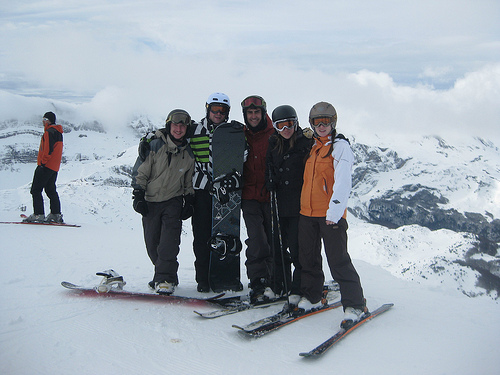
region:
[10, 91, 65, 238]
skier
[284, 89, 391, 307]
skier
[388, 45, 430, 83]
white clouds in blue sky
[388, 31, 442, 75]
white clouds in blue sky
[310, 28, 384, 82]
white clouds in blue sky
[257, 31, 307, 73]
white clouds in blue sky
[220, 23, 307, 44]
white clouds in blue sky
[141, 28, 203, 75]
white clouds in blue sky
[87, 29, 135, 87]
white clouds in blue sky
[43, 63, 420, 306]
people in the photo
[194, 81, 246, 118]
white helmet on the man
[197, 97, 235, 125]
goggles on man's head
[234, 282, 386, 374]
skis on the ground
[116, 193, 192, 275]
pants on the person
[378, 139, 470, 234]
mountains in the background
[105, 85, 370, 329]
5 people posing for a picture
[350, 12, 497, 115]
clouds in a blue and white sky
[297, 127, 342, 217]
Orange winter jacket with white arm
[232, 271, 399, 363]
2 skis and white boots on top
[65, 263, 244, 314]
Snow board on snow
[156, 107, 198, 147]
Man smiling at camera with brown visor.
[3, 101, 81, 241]
Man on skis looking away from camera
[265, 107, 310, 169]
Girl with long brown hair and silver visor.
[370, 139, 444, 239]
Mountain with snow on it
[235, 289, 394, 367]
Woman on skis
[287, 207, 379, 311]
Woman wearing pants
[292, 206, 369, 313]
Woman is wearing pants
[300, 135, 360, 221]
Woman wearing a jacket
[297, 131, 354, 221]
Woman is wearing a jacket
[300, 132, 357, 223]
Woman wearing an orange and white jacket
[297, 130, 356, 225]
Woman is wearing an orange and white jacket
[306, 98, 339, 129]
Woman wearing a helmet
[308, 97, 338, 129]
Woman is wearing a helmet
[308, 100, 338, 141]
a grey safety ski helmet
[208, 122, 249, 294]
a grey snow board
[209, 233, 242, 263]
a snow board boot mount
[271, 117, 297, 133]
white ski goggles with amber lens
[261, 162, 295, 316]
black and grey ski poles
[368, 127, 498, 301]
mountainous area behind the skiers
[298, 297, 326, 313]
white ski boots mounted on the skis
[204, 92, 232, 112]
a white safety ski helmet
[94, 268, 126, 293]
a snowboard boot mount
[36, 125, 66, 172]
an orange and black ski jacket